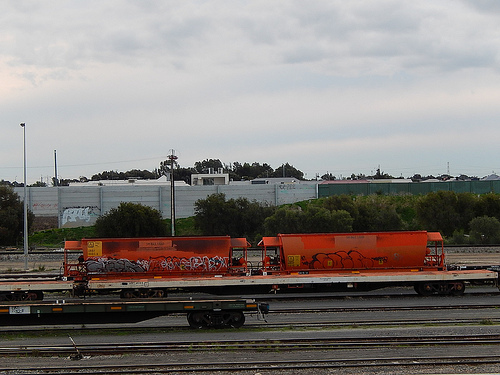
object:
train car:
[257, 230, 448, 275]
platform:
[2, 245, 499, 373]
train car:
[60, 235, 253, 281]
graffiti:
[86, 256, 229, 274]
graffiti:
[300, 251, 388, 268]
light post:
[19, 121, 29, 270]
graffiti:
[61, 205, 92, 223]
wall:
[14, 179, 500, 233]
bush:
[95, 199, 169, 237]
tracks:
[0, 242, 498, 255]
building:
[69, 168, 415, 186]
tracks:
[0, 271, 499, 373]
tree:
[1, 183, 36, 243]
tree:
[193, 192, 275, 232]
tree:
[262, 206, 353, 234]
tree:
[316, 193, 361, 231]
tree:
[416, 191, 499, 239]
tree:
[383, 192, 425, 230]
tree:
[355, 194, 387, 233]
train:
[52, 230, 446, 288]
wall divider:
[29, 186, 33, 213]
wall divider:
[57, 188, 63, 229]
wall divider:
[99, 186, 103, 218]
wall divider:
[158, 185, 161, 213]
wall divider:
[216, 183, 221, 192]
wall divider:
[275, 183, 278, 205]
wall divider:
[315, 181, 320, 196]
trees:
[193, 191, 499, 245]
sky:
[2, 2, 498, 186]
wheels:
[415, 276, 467, 294]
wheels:
[118, 288, 169, 299]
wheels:
[0, 289, 42, 299]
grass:
[2, 317, 499, 338]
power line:
[166, 147, 179, 235]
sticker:
[86, 239, 103, 258]